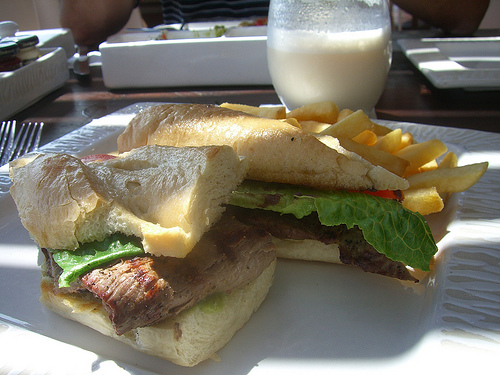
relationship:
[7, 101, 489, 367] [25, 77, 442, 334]
food on plate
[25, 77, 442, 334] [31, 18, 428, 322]
plate on table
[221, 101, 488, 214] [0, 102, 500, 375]
french fries in plate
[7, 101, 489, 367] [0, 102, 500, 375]
food on plate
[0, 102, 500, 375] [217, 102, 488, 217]
plate with fries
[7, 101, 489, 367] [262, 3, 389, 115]
food with drink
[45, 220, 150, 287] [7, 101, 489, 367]
lettuce in food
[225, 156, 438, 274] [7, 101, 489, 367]
lettuce in food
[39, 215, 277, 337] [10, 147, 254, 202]
meat in roll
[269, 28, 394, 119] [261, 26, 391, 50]
drink with froth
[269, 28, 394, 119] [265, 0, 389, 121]
drink in clear glass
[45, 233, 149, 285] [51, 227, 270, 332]
lettuce on steak.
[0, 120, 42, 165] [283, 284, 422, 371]
fork next to plate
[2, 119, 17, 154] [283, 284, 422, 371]
fork next to plate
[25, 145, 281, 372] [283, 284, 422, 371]
food next to plate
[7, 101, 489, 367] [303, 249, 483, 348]
food on plate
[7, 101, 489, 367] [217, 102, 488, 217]
food with fries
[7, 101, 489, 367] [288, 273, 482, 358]
food with plate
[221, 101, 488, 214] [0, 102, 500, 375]
french fries on plate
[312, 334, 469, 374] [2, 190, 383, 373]
sunlight on white plate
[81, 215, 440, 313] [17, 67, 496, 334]
meat on sandwich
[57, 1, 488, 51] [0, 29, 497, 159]
person at table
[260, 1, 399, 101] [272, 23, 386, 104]
clear glass of milk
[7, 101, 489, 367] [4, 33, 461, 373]
food on table